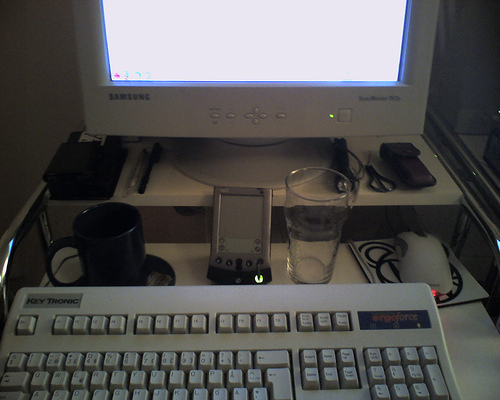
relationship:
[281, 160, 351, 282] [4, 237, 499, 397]
glass on desk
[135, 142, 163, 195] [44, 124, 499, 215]
pen on desk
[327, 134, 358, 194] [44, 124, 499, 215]
pen on desk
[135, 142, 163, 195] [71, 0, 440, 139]
pen under computer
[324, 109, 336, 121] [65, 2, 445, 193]
power light on monitor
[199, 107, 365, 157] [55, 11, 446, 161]
buttons on front of monitor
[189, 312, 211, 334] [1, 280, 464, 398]
key on laptop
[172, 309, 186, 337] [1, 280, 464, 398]
key on laptop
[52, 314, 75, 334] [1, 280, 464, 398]
key on laptop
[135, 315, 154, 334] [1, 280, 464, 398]
key on laptop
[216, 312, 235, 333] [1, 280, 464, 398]
key on laptop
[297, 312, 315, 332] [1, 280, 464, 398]
key on laptop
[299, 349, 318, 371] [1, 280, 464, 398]
key on laptop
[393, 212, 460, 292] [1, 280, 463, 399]
mouse sitting next to keypad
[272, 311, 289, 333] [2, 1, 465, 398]
key built into laptop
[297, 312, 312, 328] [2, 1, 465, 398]
key built into laptop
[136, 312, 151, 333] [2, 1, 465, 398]
key built into laptop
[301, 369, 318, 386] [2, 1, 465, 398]
key built into laptop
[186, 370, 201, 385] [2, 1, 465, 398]
key built into laptop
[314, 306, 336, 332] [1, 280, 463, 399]
key built into keypad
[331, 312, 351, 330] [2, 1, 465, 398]
key built into laptop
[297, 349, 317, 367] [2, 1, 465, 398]
key built into laptop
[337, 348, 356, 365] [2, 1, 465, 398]
key built into laptop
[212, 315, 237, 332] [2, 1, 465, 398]
key built into laptop